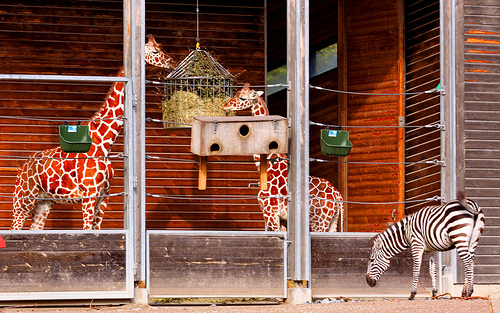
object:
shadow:
[143, 186, 243, 237]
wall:
[0, 0, 290, 236]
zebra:
[364, 191, 487, 245]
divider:
[0, 228, 446, 291]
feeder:
[312, 118, 440, 165]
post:
[286, 0, 313, 306]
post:
[437, 0, 463, 231]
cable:
[306, 85, 457, 97]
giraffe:
[10, 32, 180, 230]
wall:
[335, 0, 412, 229]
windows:
[266, 40, 343, 95]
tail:
[454, 192, 481, 215]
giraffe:
[219, 83, 348, 233]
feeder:
[163, 31, 242, 140]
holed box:
[188, 114, 287, 156]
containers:
[59, 120, 354, 157]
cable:
[308, 85, 442, 96]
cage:
[2, 3, 441, 223]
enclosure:
[6, 3, 496, 295]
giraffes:
[9, 33, 346, 233]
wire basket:
[163, 28, 245, 129]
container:
[59, 122, 92, 152]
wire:
[33, 120, 126, 126]